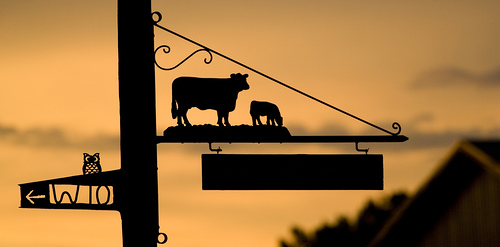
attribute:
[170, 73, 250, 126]
cow — metal, large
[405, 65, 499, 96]
clouds — gray, here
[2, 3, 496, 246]
sky — yellow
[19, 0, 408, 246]
sign — post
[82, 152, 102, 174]
owl — small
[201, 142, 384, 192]
plate — dangling, hanging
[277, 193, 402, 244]
trees — green, outlined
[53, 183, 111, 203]
owl — backwards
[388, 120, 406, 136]
end — curled